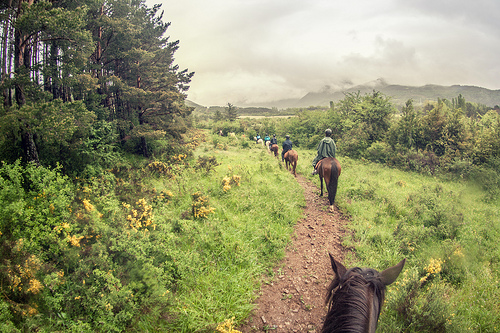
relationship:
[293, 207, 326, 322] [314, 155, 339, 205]
trail for riding horse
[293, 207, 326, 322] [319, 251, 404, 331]
trail for riding horse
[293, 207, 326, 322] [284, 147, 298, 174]
trail for riding horse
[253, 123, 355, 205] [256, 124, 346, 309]
people riding horses over a path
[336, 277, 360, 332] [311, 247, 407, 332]
mane of a horse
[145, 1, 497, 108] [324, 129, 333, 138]
sky over head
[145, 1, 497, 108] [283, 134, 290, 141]
sky over head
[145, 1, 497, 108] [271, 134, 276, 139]
sky over head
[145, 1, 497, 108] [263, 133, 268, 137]
sky over head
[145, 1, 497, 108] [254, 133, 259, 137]
sky over head